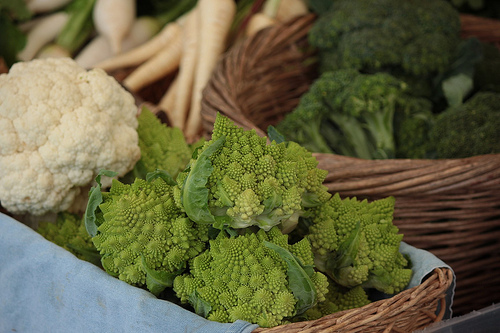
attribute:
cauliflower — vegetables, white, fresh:
[0, 54, 147, 215]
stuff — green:
[171, 110, 331, 232]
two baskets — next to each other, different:
[2, 1, 499, 332]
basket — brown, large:
[197, 8, 499, 318]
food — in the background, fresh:
[270, 2, 500, 158]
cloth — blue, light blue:
[0, 212, 459, 332]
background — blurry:
[1, 1, 498, 165]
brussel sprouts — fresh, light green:
[35, 110, 417, 331]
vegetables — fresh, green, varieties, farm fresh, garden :
[0, 1, 500, 328]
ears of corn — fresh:
[4, 0, 307, 137]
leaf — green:
[189, 139, 223, 228]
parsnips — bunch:
[2, 1, 279, 136]